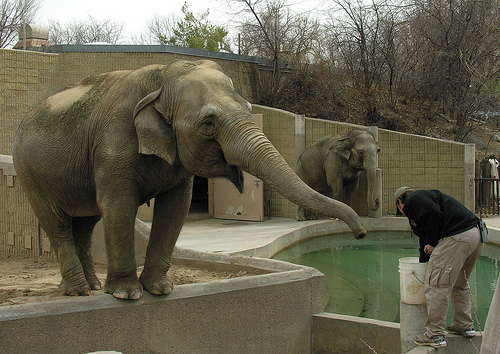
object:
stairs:
[324, 253, 400, 321]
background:
[1, 1, 499, 225]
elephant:
[9, 57, 368, 301]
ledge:
[1, 274, 252, 327]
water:
[269, 228, 499, 332]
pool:
[265, 215, 500, 326]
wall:
[250, 101, 476, 218]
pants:
[420, 226, 484, 337]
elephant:
[290, 125, 380, 220]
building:
[0, 20, 476, 220]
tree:
[1, 0, 42, 50]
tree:
[43, 15, 126, 45]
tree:
[156, 1, 229, 51]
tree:
[211, 0, 326, 112]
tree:
[322, 1, 408, 131]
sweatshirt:
[400, 185, 483, 264]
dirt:
[0, 250, 203, 297]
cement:
[298, 305, 412, 345]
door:
[207, 108, 269, 221]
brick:
[428, 133, 458, 165]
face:
[165, 79, 275, 192]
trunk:
[241, 144, 370, 240]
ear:
[131, 93, 177, 165]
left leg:
[143, 182, 198, 295]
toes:
[99, 276, 146, 301]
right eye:
[202, 113, 218, 126]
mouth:
[225, 161, 252, 193]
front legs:
[103, 178, 147, 299]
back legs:
[36, 204, 97, 296]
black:
[398, 190, 480, 250]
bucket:
[395, 256, 429, 306]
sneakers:
[409, 327, 451, 348]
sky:
[28, 0, 336, 43]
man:
[392, 177, 484, 350]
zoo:
[0, 0, 498, 352]